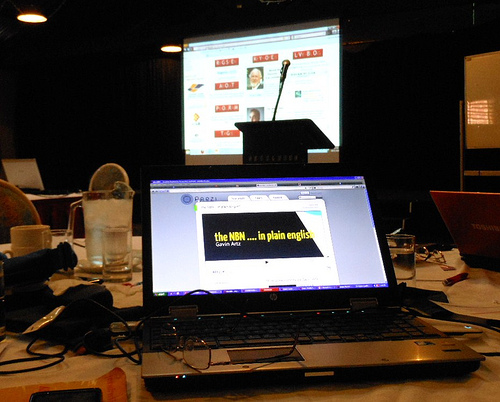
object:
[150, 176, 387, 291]
screen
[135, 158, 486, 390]
laptop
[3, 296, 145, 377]
cord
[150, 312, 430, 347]
keys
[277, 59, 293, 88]
microphone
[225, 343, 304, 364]
touchpad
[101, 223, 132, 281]
glass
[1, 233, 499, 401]
table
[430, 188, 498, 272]
laptop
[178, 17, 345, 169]
projection screen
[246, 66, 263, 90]
image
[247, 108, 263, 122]
man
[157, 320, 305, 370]
glasses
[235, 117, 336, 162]
podium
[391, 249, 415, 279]
water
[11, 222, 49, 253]
mug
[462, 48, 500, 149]
board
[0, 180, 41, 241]
chair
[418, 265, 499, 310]
paper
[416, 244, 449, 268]
glasses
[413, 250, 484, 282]
paper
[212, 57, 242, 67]
symbol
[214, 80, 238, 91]
symbol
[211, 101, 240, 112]
symbol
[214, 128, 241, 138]
symbol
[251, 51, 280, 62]
symbol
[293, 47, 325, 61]
symbol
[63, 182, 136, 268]
water pitcher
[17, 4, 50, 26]
light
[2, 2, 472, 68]
ceiling